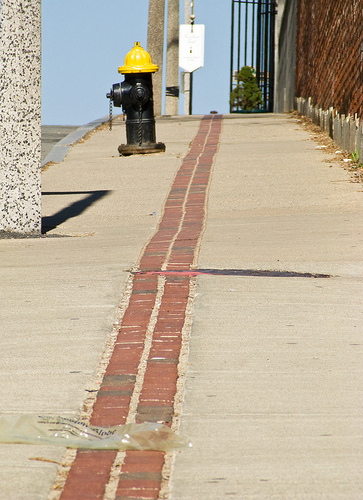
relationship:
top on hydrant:
[114, 37, 162, 73] [106, 39, 167, 155]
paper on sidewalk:
[2, 410, 191, 455] [0, 109, 360, 499]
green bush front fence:
[230, 65, 264, 112] [229, 0, 275, 114]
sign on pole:
[176, 21, 208, 73] [186, 67, 195, 109]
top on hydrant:
[116, 40, 158, 75] [106, 39, 167, 155]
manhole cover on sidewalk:
[127, 261, 333, 281] [0, 109, 360, 499]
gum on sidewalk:
[205, 475, 230, 486] [127, 167, 310, 427]